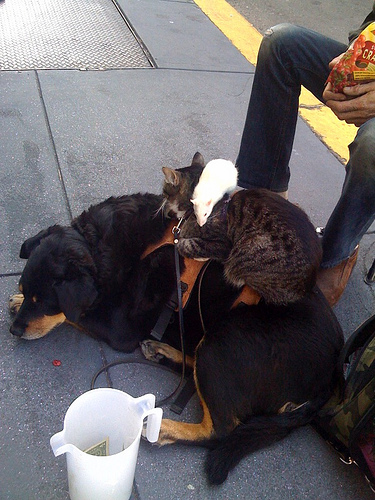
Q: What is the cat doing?
A: Laying on top of the dog.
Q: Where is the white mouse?
A: On top of the cat.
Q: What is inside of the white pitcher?
A: Money.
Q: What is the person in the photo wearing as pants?
A: Blue jeans.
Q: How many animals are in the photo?
A: Three animals.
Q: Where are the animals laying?
A: They are laying on pavement.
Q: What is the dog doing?
A: Laying down.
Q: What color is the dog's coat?
A: Black and brown.